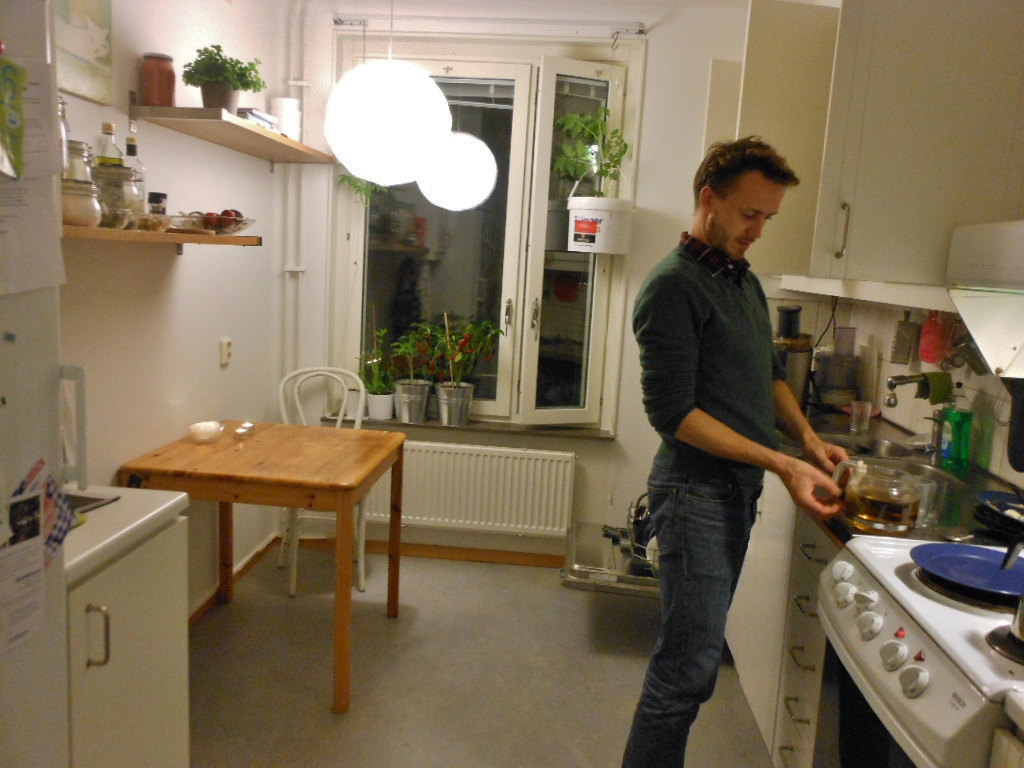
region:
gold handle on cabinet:
[825, 188, 864, 269]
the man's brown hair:
[680, 138, 826, 187]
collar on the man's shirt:
[676, 226, 756, 288]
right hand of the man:
[778, 458, 842, 526]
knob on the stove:
[893, 659, 936, 699]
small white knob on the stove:
[866, 633, 909, 678]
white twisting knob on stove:
[852, 611, 892, 650]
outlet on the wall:
[212, 328, 251, 363]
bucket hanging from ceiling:
[555, 186, 650, 270]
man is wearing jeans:
[638, 435, 734, 762]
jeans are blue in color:
[632, 458, 801, 762]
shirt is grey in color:
[606, 224, 772, 481]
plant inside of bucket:
[562, 110, 635, 186]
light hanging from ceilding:
[333, 45, 466, 191]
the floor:
[455, 669, 536, 743]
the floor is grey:
[442, 620, 537, 729]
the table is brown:
[269, 428, 355, 479]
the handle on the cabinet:
[89, 605, 122, 663]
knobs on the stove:
[873, 642, 959, 710]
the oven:
[819, 686, 864, 751]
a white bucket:
[569, 198, 626, 244]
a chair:
[278, 371, 362, 423]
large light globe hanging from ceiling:
[319, 51, 457, 194]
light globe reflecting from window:
[414, 127, 500, 220]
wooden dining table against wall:
[110, 413, 412, 721]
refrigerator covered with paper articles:
[2, 3, 92, 766]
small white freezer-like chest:
[63, 478, 204, 766]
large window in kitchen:
[316, 37, 633, 431]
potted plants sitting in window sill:
[359, 307, 503, 431]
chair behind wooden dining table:
[271, 360, 379, 604]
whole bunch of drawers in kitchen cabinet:
[771, 522, 828, 766]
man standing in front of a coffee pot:
[621, 134, 923, 764]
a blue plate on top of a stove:
[819, 538, 1022, 764]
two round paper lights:
[324, 2, 495, 214]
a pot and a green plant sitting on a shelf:
[124, 46, 337, 168]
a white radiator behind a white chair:
[276, 366, 570, 591]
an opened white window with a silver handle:
[519, 59, 630, 430]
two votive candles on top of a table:
[128, 415, 403, 720]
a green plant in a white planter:
[552, 105, 638, 257]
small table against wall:
[108, 397, 422, 729]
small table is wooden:
[93, 398, 427, 730]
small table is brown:
[108, 406, 416, 742]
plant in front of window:
[379, 317, 444, 432]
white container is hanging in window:
[560, 160, 633, 262]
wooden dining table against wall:
[110, 414, 408, 719]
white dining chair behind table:
[258, 366, 388, 601]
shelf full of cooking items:
[50, 94, 270, 254]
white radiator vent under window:
[284, 423, 579, 547]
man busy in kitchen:
[619, 133, 855, 766]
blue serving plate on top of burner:
[903, 535, 1022, 605]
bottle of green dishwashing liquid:
[935, 377, 978, 472]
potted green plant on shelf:
[180, 38, 269, 121]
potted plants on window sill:
[359, 303, 509, 431]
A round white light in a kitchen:
[324, 51, 461, 184]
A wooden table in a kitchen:
[131, 411, 404, 703]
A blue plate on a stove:
[914, 537, 1022, 598]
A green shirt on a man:
[633, 238, 782, 495]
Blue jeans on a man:
[631, 462, 764, 766]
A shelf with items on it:
[54, 102, 269, 242]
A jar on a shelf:
[143, 45, 179, 104]